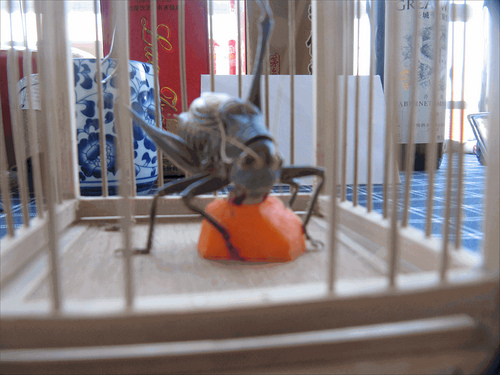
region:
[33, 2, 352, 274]
insect eating food in cage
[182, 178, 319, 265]
orange piece of carrot in cage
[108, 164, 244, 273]
two insect legs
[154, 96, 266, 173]
insect antenna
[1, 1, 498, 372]
white cage in room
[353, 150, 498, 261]
blue and white square tiled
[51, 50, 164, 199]
blue and white porcelain mug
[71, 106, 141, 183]
floral pattern on porcelain mug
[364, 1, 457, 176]
wine bottle with white label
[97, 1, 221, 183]
red and gold rectangular box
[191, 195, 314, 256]
piece of orange carrot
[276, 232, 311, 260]
cut edge of the carrot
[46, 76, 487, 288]
silver pen holding gray bug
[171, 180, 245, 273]
small black bug's hand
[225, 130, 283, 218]
face of the bug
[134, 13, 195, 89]
gold symbols on the wall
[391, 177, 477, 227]
blue and white color on the floor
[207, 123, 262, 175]
white tentacles on bug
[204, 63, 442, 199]
large section of white board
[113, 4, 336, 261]
a grasshopper is on a piece of fruit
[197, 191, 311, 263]
the fruit is a peeled papaya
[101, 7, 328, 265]
the grasshopper is gray and black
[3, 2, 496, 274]
the enclosure has white wood spindles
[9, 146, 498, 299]
the tablecloth has blue and white checks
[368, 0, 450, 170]
a bottle of wine is on the table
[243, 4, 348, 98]
a bottle of sake is on the table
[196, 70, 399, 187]
a white envelope is on the table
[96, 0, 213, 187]
a red labeled bottle is behind the grasshopper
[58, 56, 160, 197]
a blue and white vase is on the table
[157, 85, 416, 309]
a bug is eating fruit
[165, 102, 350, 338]
the fruit is red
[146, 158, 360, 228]
the bug has long legs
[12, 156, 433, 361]
the bug is in a cage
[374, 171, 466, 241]
the floor is tiled blue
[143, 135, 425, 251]
the bug has wings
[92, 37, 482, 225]
the bug has several legs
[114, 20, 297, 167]
a red wall is behind the bug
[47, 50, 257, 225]
a blue cup is behind the bug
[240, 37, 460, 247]
a white envelope is behind the bug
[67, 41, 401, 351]
a creature in a cage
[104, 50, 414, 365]
a small creature in a cage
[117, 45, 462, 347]
a creature eating someting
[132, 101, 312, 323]
creature eating something orange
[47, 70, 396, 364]
a small creature eating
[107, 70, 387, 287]
a small creature eating an orange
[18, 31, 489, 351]
a create in a white cage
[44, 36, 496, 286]
a creature in a metal cage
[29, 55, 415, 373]
creature in a metal white cage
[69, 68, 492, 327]
a metal white cage